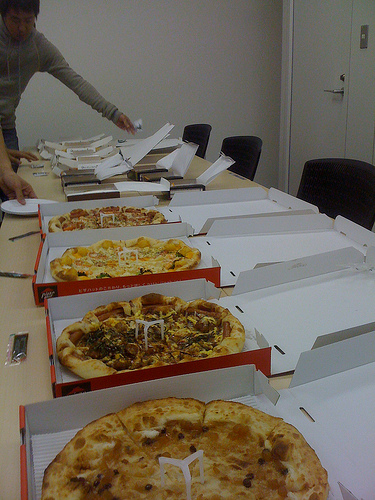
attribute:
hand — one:
[0, 145, 41, 169]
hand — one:
[0, 135, 43, 206]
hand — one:
[107, 108, 139, 136]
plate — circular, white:
[0, 192, 67, 217]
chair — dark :
[298, 159, 374, 231]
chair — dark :
[219, 135, 262, 178]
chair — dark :
[180, 123, 208, 157]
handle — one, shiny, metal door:
[326, 85, 345, 97]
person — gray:
[2, 0, 136, 147]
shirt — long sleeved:
[2, 35, 118, 131]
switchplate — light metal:
[338, 17, 371, 72]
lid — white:
[236, 177, 286, 277]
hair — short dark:
[0, 1, 38, 41]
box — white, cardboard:
[39, 182, 318, 240]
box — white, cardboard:
[32, 207, 374, 306]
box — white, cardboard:
[46, 245, 373, 400]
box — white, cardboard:
[18, 328, 373, 494]